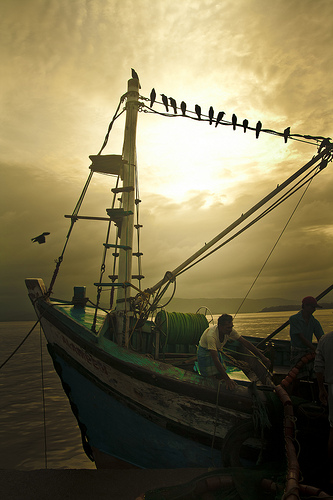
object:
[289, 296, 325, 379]
man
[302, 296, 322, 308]
hat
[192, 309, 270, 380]
man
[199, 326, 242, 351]
shirt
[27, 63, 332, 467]
boat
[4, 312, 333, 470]
ocean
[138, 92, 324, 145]
line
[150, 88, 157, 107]
bird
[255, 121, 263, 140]
bird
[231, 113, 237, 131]
bird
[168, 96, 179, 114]
bird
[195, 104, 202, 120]
bird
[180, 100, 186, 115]
bird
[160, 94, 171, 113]
bird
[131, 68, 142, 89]
bird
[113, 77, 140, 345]
mast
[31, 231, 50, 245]
bird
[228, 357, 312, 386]
deck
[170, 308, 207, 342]
rope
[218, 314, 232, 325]
hair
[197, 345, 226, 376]
apron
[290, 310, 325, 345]
shirt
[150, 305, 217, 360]
spool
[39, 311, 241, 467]
side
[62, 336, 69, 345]
letters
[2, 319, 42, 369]
rope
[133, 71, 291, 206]
sun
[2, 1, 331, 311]
sky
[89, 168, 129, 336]
ladder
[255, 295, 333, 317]
mountains